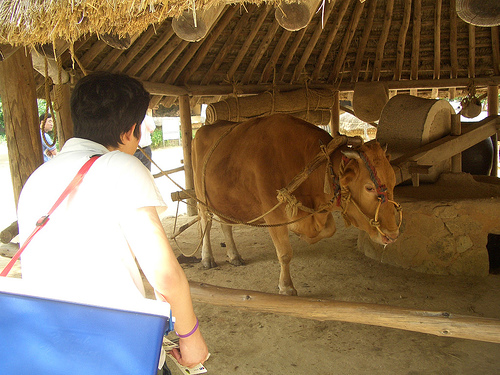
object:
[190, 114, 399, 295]
cow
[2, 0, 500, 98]
roof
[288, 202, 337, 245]
chest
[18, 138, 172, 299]
shirt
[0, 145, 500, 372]
ground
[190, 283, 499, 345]
pole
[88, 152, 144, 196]
shoulder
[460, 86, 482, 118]
bag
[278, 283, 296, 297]
hoofs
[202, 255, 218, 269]
hoofs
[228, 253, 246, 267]
hoofs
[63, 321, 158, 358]
blue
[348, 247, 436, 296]
floor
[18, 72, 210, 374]
person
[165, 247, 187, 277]
part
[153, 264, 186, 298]
elbow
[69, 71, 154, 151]
hair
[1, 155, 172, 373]
bag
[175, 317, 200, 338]
band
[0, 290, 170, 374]
kit